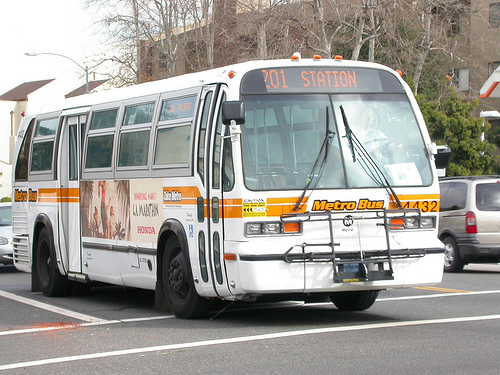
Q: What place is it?
A: It is a street.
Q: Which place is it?
A: It is a street.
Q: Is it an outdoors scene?
A: Yes, it is outdoors.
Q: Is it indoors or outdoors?
A: It is outdoors.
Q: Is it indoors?
A: No, it is outdoors.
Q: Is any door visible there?
A: Yes, there is a door.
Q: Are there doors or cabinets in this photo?
A: Yes, there is a door.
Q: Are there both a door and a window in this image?
A: Yes, there are both a door and a window.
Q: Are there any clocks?
A: No, there are no clocks.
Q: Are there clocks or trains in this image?
A: No, there are no clocks or trains.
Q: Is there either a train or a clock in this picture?
A: No, there are no clocks or trains.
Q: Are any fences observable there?
A: No, there are no fences.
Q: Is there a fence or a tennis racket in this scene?
A: No, there are no fences or rackets.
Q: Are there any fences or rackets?
A: No, there are no fences or rackets.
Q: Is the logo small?
A: Yes, the logo is small.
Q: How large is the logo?
A: The logo is small.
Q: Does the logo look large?
A: No, the logo is small.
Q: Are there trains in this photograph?
A: No, there are no trains.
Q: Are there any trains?
A: No, there are no trains.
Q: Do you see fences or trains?
A: No, there are no trains or fences.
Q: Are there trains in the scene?
A: No, there are no trains.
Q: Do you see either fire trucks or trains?
A: No, there are no trains or fire trucks.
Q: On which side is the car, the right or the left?
A: The car is on the left of the image.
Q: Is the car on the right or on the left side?
A: The car is on the left of the image.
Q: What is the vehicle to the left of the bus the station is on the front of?
A: The vehicle is a car.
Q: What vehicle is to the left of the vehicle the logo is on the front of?
A: The vehicle is a car.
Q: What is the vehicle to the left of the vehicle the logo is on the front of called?
A: The vehicle is a car.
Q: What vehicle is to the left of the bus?
A: The vehicle is a car.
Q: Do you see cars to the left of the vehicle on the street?
A: Yes, there is a car to the left of the bus.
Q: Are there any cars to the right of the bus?
A: No, the car is to the left of the bus.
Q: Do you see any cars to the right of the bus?
A: No, the car is to the left of the bus.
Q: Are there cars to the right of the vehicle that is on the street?
A: No, the car is to the left of the bus.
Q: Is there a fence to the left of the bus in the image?
A: No, there is a car to the left of the bus.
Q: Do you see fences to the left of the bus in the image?
A: No, there is a car to the left of the bus.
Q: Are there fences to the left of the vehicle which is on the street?
A: No, there is a car to the left of the bus.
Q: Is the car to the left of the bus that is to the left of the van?
A: Yes, the car is to the left of the bus.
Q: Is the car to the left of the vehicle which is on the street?
A: Yes, the car is to the left of the bus.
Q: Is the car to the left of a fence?
A: No, the car is to the left of the bus.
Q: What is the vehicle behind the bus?
A: The vehicle is a car.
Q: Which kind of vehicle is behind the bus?
A: The vehicle is a car.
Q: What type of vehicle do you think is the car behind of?
A: The car is behind the bus.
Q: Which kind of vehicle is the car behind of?
A: The car is behind the bus.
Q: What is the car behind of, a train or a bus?
A: The car is behind a bus.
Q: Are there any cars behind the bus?
A: Yes, there is a car behind the bus.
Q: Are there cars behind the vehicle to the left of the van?
A: Yes, there is a car behind the bus.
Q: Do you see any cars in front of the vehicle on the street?
A: No, the car is behind the bus.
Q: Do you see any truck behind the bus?
A: No, there is a car behind the bus.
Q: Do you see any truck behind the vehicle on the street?
A: No, there is a car behind the bus.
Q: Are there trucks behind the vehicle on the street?
A: No, there is a car behind the bus.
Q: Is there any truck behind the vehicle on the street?
A: No, there is a car behind the bus.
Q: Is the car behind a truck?
A: No, the car is behind the bus.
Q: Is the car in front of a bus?
A: No, the car is behind a bus.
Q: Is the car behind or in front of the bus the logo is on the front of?
A: The car is behind the bus.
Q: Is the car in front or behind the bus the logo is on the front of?
A: The car is behind the bus.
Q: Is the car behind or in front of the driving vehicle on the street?
A: The car is behind the bus.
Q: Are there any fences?
A: No, there are no fences.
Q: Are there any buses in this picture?
A: Yes, there is a bus.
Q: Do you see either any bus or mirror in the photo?
A: Yes, there is a bus.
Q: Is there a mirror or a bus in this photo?
A: Yes, there is a bus.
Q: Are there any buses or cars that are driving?
A: Yes, the bus is driving.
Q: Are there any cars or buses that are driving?
A: Yes, the bus is driving.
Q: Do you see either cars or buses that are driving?
A: Yes, the bus is driving.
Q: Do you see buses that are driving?
A: Yes, there is a bus that is driving.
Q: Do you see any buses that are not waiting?
A: Yes, there is a bus that is driving .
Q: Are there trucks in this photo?
A: No, there are no trucks.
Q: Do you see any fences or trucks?
A: No, there are no trucks or fences.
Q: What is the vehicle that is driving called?
A: The vehicle is a bus.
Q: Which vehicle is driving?
A: The vehicle is a bus.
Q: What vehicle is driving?
A: The vehicle is a bus.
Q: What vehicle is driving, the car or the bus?
A: The bus is driving.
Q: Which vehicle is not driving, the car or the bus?
A: The car is not driving.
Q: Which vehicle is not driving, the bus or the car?
A: The car is not driving.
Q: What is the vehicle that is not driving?
A: The vehicle is a car.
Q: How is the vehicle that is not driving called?
A: The vehicle is a car.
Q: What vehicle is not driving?
A: The vehicle is a car.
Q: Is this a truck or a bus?
A: This is a bus.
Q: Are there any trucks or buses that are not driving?
A: No, there is a bus but it is driving.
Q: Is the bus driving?
A: Yes, the bus is driving.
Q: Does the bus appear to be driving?
A: Yes, the bus is driving.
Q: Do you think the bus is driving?
A: Yes, the bus is driving.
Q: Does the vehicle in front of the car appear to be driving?
A: Yes, the bus is driving.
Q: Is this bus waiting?
A: No, the bus is driving.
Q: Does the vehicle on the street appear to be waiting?
A: No, the bus is driving.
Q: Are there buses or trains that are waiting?
A: No, there is a bus but it is driving.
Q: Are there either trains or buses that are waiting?
A: No, there is a bus but it is driving.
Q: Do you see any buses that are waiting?
A: No, there is a bus but it is driving.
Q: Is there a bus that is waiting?
A: No, there is a bus but it is driving.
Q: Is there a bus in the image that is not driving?
A: No, there is a bus but it is driving.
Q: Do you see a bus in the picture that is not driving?
A: No, there is a bus but it is driving.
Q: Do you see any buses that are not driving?
A: No, there is a bus but it is driving.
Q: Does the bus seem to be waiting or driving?
A: The bus is driving.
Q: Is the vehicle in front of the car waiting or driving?
A: The bus is driving.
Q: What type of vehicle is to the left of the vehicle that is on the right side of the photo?
A: The vehicle is a bus.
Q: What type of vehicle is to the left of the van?
A: The vehicle is a bus.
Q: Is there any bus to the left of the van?
A: Yes, there is a bus to the left of the van.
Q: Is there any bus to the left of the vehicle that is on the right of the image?
A: Yes, there is a bus to the left of the van.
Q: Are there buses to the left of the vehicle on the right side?
A: Yes, there is a bus to the left of the van.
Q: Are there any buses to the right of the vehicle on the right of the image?
A: No, the bus is to the left of the van.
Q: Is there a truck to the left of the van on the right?
A: No, there is a bus to the left of the van.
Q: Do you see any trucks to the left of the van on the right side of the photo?
A: No, there is a bus to the left of the van.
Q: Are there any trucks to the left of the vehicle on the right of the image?
A: No, there is a bus to the left of the van.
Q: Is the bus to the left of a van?
A: Yes, the bus is to the left of a van.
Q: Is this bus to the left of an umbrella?
A: No, the bus is to the left of a van.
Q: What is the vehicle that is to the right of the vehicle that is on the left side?
A: The vehicle is a bus.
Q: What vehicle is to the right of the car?
A: The vehicle is a bus.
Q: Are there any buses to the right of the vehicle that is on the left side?
A: Yes, there is a bus to the right of the car.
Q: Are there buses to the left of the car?
A: No, the bus is to the right of the car.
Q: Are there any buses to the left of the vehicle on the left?
A: No, the bus is to the right of the car.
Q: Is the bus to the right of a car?
A: Yes, the bus is to the right of a car.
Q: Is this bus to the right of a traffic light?
A: No, the bus is to the right of a car.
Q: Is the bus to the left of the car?
A: No, the bus is to the right of the car.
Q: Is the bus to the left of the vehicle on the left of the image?
A: No, the bus is to the right of the car.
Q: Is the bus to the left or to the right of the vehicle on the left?
A: The bus is to the right of the car.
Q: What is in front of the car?
A: The bus is in front of the car.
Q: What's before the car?
A: The bus is in front of the car.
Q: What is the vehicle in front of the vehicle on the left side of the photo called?
A: The vehicle is a bus.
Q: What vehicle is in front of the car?
A: The vehicle is a bus.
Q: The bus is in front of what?
A: The bus is in front of the car.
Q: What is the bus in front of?
A: The bus is in front of the car.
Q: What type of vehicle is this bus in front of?
A: The bus is in front of the car.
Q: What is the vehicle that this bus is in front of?
A: The vehicle is a car.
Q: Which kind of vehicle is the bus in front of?
A: The bus is in front of the car.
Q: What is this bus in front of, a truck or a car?
A: The bus is in front of a car.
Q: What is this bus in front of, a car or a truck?
A: The bus is in front of a car.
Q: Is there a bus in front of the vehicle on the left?
A: Yes, there is a bus in front of the car.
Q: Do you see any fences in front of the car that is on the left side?
A: No, there is a bus in front of the car.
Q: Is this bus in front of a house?
A: No, the bus is in front of the car.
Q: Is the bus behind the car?
A: No, the bus is in front of the car.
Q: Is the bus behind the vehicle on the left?
A: No, the bus is in front of the car.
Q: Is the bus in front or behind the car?
A: The bus is in front of the car.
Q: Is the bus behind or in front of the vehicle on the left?
A: The bus is in front of the car.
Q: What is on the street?
A: The bus is on the street.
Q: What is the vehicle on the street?
A: The vehicle is a bus.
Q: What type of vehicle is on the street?
A: The vehicle is a bus.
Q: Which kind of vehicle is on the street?
A: The vehicle is a bus.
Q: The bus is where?
A: The bus is on the street.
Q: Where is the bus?
A: The bus is on the street.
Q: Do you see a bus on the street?
A: Yes, there is a bus on the street.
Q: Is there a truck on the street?
A: No, there is a bus on the street.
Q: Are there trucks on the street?
A: No, there is a bus on the street.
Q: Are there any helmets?
A: No, there are no helmets.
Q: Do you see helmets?
A: No, there are no helmets.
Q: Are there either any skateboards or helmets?
A: No, there are no helmets or skateboards.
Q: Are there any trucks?
A: No, there are no trucks.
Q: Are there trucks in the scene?
A: No, there are no trucks.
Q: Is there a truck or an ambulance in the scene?
A: No, there are no trucks or ambulances.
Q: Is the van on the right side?
A: Yes, the van is on the right of the image.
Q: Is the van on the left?
A: No, the van is on the right of the image.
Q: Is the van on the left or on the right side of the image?
A: The van is on the right of the image.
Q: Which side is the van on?
A: The van is on the right of the image.